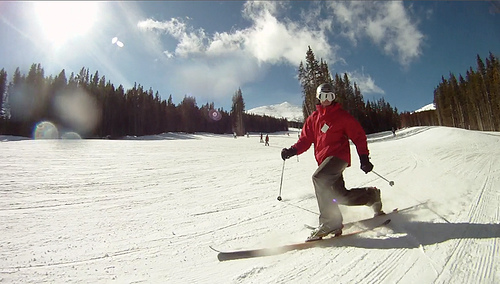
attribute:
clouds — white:
[176, 7, 378, 97]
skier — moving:
[279, 80, 411, 252]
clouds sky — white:
[137, 9, 297, 75]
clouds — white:
[139, 10, 333, 59]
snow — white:
[35, 156, 236, 247]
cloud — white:
[328, 2, 426, 70]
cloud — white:
[325, 67, 384, 102]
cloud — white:
[206, 0, 336, 74]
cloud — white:
[136, 14, 209, 64]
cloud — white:
[109, 36, 123, 48]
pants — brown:
[298, 144, 397, 239]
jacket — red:
[290, 98, 373, 160]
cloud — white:
[167, 7, 336, 77]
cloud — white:
[319, 5, 434, 68]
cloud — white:
[112, 11, 203, 68]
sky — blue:
[5, 7, 494, 119]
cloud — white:
[329, 0, 426, 64]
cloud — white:
[232, 11, 327, 53]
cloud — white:
[141, 22, 248, 104]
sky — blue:
[1, 0, 492, 54]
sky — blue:
[7, 4, 495, 139]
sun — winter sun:
[21, 0, 117, 65]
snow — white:
[114, 169, 192, 226]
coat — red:
[291, 100, 369, 166]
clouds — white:
[103, 1, 430, 58]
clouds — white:
[105, 34, 194, 60]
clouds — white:
[98, 0, 422, 91]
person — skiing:
[280, 74, 402, 237]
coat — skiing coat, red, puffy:
[285, 98, 374, 170]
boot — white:
[368, 185, 389, 216]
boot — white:
[310, 209, 345, 242]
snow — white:
[2, 128, 482, 278]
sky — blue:
[2, 3, 483, 113]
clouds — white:
[133, 25, 287, 89]